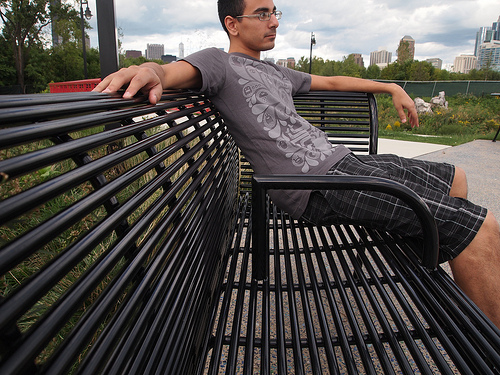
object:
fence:
[366, 78, 499, 98]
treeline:
[291, 53, 500, 82]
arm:
[138, 49, 220, 91]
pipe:
[0, 94, 123, 140]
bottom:
[195, 192, 500, 375]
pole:
[95, 0, 128, 175]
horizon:
[0, 36, 500, 66]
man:
[90, 0, 500, 330]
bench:
[0, 89, 500, 375]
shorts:
[299, 153, 488, 264]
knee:
[452, 166, 467, 186]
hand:
[90, 64, 162, 105]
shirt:
[175, 46, 352, 220]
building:
[370, 50, 393, 66]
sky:
[286, 0, 470, 32]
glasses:
[231, 10, 283, 21]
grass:
[423, 121, 469, 135]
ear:
[224, 15, 239, 36]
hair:
[217, 0, 247, 40]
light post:
[309, 31, 317, 74]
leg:
[320, 160, 499, 329]